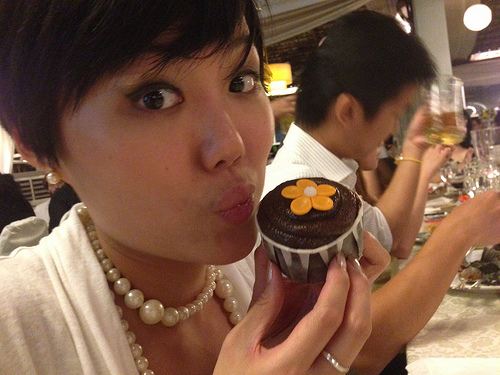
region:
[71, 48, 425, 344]
woman holding a cupcake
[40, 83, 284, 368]
woman is wearing pearl necklaces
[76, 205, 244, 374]
woman wearing a pearl necklace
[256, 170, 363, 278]
woman holding a small cupcake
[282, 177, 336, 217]
an orange candied flower on a cupcake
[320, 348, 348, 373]
woman wearing a silver ring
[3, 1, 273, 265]
woman with short dark brown hair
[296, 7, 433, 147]
a man with short dark brown hair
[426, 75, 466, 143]
a glass with amber liquid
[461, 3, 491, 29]
a white light on the ceiling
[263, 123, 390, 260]
man wearing a white button-down shirt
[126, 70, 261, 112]
woman with almond shape eyes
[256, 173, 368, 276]
chocolate cake with orange flower decoration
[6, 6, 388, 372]
young woman shows off chocolate pastry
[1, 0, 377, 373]
young woman holding chocolate cake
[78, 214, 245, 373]
pearl necklace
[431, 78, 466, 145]
mug of light colored beer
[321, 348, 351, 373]
woman's ring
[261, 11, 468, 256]
young man raising mug of beer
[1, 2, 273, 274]
young woman's face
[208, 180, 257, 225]
young woman's lips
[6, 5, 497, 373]
young people enjoying themselves at a dining table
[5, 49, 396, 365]
a woman holding a cup cake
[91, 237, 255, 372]
a pearl necklace around a neck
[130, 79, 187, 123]
an eye of a woman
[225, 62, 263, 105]
an eye of a woman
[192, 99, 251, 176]
a nose of a woman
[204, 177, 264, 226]
the lips of a woman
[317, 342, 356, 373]
a ring on a finger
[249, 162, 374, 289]
a chocolate with an orange frosting flower on top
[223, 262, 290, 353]
the thumb of a hand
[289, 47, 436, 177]
the head of aman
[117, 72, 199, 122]
The eye is brown.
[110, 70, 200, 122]
The eye is open.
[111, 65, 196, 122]
Brown eye shadow above eye.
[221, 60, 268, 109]
The eye is brown.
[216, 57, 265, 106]
The eye is open.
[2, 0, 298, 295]
The woman has two eyes.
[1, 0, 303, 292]
The woman has short hair.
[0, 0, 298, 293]
The woman has dark hair.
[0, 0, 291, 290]
The woman is wearing an earring.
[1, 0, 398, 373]
The woman is holding a cupcake.